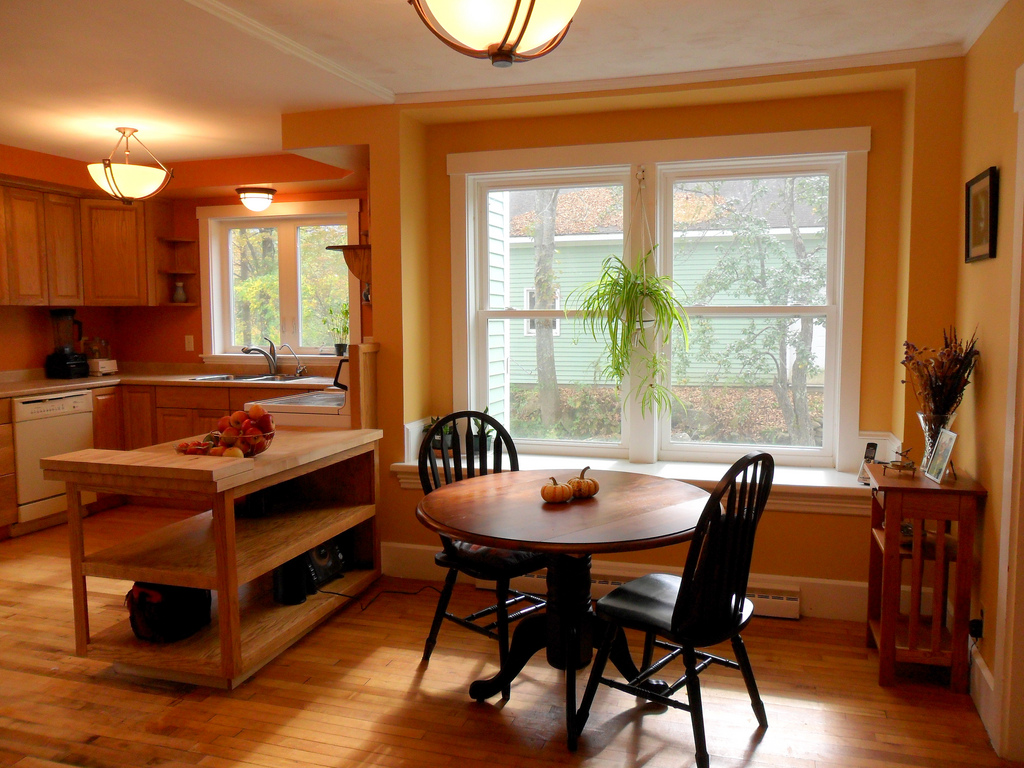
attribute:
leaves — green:
[571, 241, 688, 412]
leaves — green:
[642, 323, 671, 410]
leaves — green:
[716, 187, 773, 251]